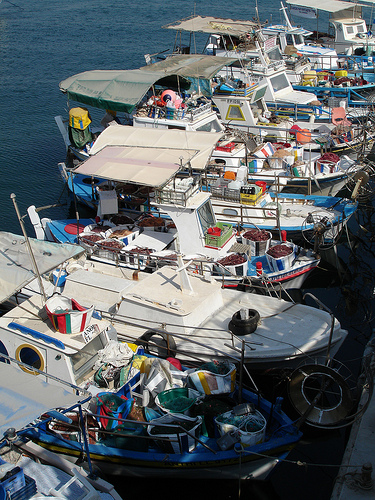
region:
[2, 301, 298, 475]
a blue and white boat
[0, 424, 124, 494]
a blue and white boat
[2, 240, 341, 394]
a white boat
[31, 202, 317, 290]
a red blue and white boat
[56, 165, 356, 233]
a blue and white boat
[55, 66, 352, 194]
a white boat with green canopy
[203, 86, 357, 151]
a white and yellow boat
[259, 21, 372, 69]
a blue and white boat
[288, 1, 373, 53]
a white covered boat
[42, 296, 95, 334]
a red white and green basket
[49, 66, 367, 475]
Group of boats sitting in the water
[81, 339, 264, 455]
Stack of bags sitting on front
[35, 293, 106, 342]
Basket on top of boat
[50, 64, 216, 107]
Cover on the top of boat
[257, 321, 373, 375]
Rope tying to the boat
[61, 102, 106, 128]
Yellow basket flipped upside down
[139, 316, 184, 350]
Metal ring on side of boat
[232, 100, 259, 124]
Yellow window on side of boat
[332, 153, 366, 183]
Fan on front of boat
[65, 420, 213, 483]
Blue paint on the boat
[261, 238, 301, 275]
white and blue bin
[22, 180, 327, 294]
boat docked with other boats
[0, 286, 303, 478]
boat docked with other boats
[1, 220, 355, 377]
boat docked with other boats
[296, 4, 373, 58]
boat docked with other boats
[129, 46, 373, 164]
boat docked with other boats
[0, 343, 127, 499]
boat docked with other boats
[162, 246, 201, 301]
communication antenna on a boat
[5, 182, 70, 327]
metal pole on a boat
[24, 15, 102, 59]
The water is blue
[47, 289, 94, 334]
The basket is red white and green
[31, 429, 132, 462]
The paint is yellow and blue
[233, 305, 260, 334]
The basket is brown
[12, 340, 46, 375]
A window with yellow trim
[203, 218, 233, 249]
The basket is green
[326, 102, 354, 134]
The chair is pink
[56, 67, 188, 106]
A green canopy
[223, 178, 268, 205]
Red yellow and gray baskets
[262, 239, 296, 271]
Lobsters are in the box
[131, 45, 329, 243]
boats lined up next to each other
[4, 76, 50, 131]
water behind the boat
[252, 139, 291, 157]
stuff in the boat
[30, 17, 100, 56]
ripples in the water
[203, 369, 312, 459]
front of the boat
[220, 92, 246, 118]
window on the boat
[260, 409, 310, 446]
tip of the boat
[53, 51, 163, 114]
top of the boat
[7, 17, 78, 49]
blue water behind the boats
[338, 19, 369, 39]
two windows on the boat